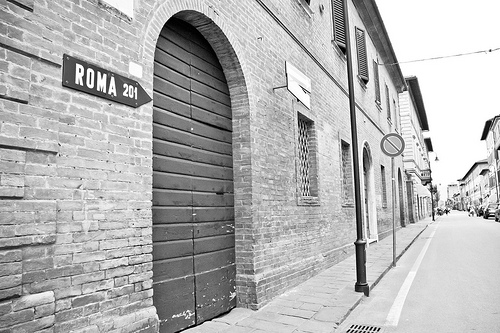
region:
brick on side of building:
[77, 184, 108, 196]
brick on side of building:
[58, 224, 86, 234]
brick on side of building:
[8, 246, 45, 261]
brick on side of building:
[28, 141, 58, 153]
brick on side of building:
[111, 137, 141, 148]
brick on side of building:
[23, 129, 53, 138]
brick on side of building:
[73, 97, 103, 107]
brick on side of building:
[24, 108, 64, 117]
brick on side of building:
[131, 288, 152, 298]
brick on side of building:
[129, 235, 154, 247]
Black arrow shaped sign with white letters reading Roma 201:
[61, 45, 154, 104]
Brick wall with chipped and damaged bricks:
[61, 132, 157, 286]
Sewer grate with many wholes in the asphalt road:
[345, 318, 390, 331]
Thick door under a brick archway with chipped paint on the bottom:
[145, 0, 244, 332]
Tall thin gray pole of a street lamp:
[334, 18, 369, 295]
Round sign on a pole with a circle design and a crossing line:
[374, 127, 411, 269]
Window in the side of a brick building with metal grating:
[288, 98, 323, 210]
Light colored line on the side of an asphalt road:
[385, 273, 427, 328]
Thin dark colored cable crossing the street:
[380, 46, 485, 71]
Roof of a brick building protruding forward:
[404, 61, 435, 137]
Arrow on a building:
[47, 40, 176, 138]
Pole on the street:
[330, 68, 394, 303]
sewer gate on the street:
[327, 302, 390, 331]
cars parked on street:
[468, 194, 498, 220]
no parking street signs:
[365, 125, 425, 272]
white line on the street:
[385, 223, 417, 331]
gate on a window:
[286, 115, 318, 202]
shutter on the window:
[352, 18, 377, 93]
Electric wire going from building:
[406, 43, 498, 66]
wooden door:
[152, 175, 239, 317]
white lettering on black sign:
[61, 57, 151, 108]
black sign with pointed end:
[53, 50, 149, 112]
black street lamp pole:
[339, 6, 371, 289]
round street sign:
[379, 134, 404, 156]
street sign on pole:
[377, 131, 404, 262]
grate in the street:
[345, 319, 377, 331]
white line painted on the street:
[375, 207, 460, 324]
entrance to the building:
[144, 22, 247, 331]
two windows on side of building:
[295, 114, 358, 208]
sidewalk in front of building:
[217, 199, 443, 331]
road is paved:
[363, 207, 497, 329]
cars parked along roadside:
[473, 198, 498, 225]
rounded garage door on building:
[143, 4, 259, 331]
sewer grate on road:
[342, 322, 385, 332]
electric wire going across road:
[378, 43, 498, 75]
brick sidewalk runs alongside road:
[165, 212, 435, 331]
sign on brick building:
[58, 52, 152, 109]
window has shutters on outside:
[353, 23, 370, 90]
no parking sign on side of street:
[378, 130, 408, 269]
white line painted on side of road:
[381, 208, 442, 326]